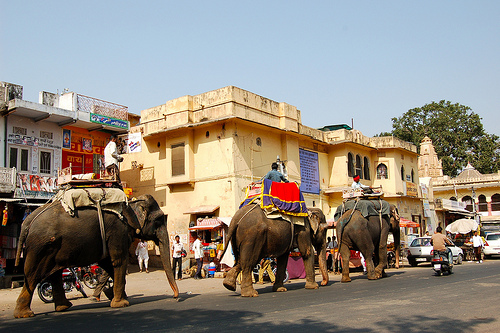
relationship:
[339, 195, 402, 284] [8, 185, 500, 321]
elephant in parade.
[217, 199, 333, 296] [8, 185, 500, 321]
elephant in parade.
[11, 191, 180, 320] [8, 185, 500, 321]
elephants in parade.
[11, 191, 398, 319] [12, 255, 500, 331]
elephants on street.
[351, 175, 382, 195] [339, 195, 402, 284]
man on elephant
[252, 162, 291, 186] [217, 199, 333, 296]
man on elephant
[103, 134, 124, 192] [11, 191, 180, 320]
man on elephants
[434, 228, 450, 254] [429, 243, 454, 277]
man riding moped.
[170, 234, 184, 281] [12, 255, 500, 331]
man in street.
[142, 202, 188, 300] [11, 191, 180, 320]
trunk on elephants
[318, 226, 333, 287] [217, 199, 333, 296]
trunk on elephant.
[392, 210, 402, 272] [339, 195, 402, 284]
trunk on elephant.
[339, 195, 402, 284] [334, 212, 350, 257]
elephant has tail.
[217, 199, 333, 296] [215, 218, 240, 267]
elephant has tail.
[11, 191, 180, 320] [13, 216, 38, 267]
elephants has tail.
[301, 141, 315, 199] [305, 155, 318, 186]
sign has writing.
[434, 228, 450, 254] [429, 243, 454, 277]
man rides moped.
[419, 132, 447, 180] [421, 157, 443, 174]
tower of stone.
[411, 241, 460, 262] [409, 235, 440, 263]
car has back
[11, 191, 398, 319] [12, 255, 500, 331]
elephants in street.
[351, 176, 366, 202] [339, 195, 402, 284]
man riding elephant.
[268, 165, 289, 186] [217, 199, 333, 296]
man riding elephant.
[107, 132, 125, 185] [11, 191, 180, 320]
man riding elephants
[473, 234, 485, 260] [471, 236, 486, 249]
man wearing shirt.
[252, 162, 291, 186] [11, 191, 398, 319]
man riding elephants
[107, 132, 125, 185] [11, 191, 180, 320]
man on elephants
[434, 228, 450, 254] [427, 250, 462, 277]
man riding moped.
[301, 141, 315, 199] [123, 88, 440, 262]
sign on building.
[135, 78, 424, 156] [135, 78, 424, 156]
roof. on roof.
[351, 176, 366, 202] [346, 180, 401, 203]
man on saddle.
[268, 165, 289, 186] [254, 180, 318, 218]
man on saddle.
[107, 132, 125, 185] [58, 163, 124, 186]
man on saddle.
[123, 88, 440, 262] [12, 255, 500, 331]
building beside road.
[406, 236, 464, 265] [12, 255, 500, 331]
car on road.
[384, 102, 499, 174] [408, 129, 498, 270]
tree behind building.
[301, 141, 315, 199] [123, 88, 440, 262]
sign on building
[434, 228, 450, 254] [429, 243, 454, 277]
man on moped.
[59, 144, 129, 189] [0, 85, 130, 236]
balcony on building.